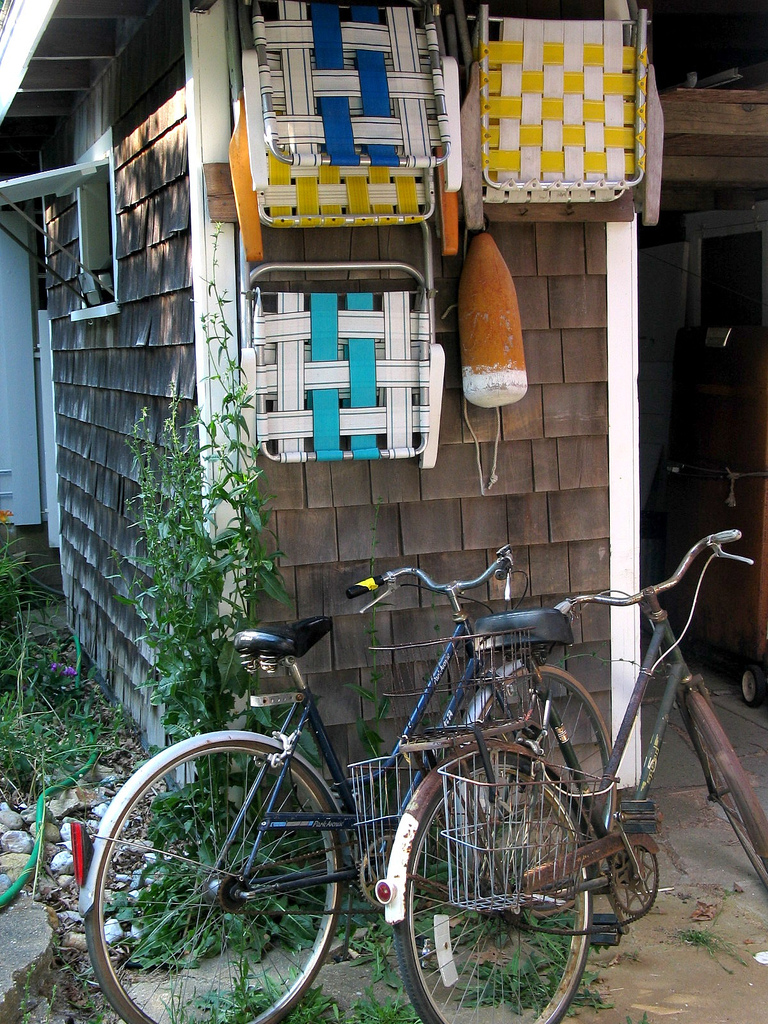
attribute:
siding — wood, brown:
[530, 479, 602, 553]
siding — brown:
[499, 483, 556, 550]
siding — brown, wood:
[456, 486, 518, 562]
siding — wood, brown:
[326, 496, 406, 572]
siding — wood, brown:
[272, 503, 348, 563]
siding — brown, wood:
[368, 451, 421, 508]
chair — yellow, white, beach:
[478, 58, 660, 219]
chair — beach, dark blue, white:
[260, 60, 454, 160]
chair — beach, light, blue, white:
[249, 276, 433, 443]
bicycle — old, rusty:
[376, 529, 715, 989]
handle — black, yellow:
[158, 513, 709, 1001]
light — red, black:
[51, 812, 101, 894]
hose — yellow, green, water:
[6, 773, 93, 845]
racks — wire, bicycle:
[284, 741, 609, 897]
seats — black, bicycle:
[259, 604, 557, 657]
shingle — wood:
[471, 450, 532, 501]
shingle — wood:
[424, 444, 471, 492]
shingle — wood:
[399, 502, 491, 553]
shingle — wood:
[326, 505, 415, 570]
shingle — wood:
[269, 497, 354, 575]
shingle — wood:
[302, 464, 391, 510]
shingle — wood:
[266, 457, 341, 512]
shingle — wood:
[253, 459, 338, 526]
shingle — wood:
[394, 434, 561, 547]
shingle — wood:
[521, 270, 546, 328]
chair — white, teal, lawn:
[202, 216, 460, 477]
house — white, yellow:
[378, 439, 580, 584]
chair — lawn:
[473, 23, 665, 228]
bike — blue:
[129, 575, 564, 945]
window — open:
[6, 152, 120, 290]